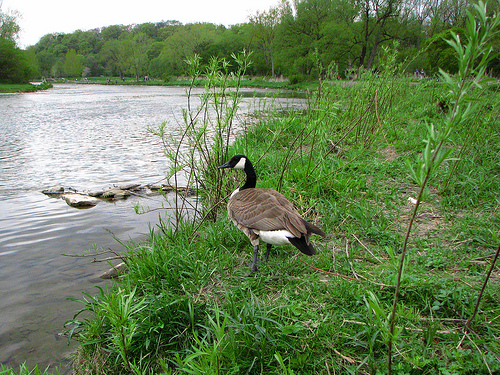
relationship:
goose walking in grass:
[215, 147, 337, 282] [82, 24, 498, 371]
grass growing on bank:
[63, 231, 209, 352] [75, 76, 497, 368]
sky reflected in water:
[3, 2, 273, 39] [1, 74, 321, 372]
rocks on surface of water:
[41, 182, 199, 207] [0, 64, 342, 346]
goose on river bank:
[215, 147, 337, 282] [0, 75, 319, 94]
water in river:
[4, 67, 266, 211] [0, 74, 312, 374]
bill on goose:
[216, 158, 230, 173] [217, 153, 323, 283]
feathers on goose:
[286, 234, 317, 256] [214, 148, 330, 272]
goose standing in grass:
[218, 154, 327, 277] [82, 24, 498, 371]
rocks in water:
[41, 172, 199, 207] [1, 74, 321, 372]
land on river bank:
[327, 71, 365, 89] [14, 60, 459, 107]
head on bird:
[212, 151, 261, 187] [206, 148, 326, 271]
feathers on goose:
[260, 222, 309, 258] [215, 147, 337, 282]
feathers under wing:
[260, 222, 309, 258] [230, 176, 325, 259]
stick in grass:
[365, 115, 448, 372] [63, 231, 209, 352]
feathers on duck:
[290, 234, 317, 257] [206, 153, 330, 282]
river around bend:
[5, 74, 202, 291] [6, 80, 347, 369]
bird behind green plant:
[206, 148, 326, 271] [130, 46, 256, 223]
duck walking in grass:
[215, 153, 328, 275] [82, 24, 498, 371]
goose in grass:
[218, 154, 327, 277] [82, 24, 498, 371]